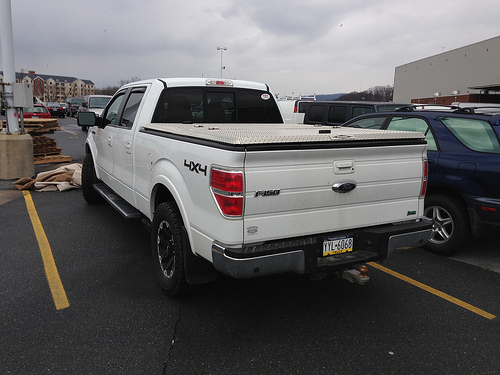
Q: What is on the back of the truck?
A: Silver cover.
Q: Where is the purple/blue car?
A: Right of the truck.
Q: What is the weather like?
A: Rainy.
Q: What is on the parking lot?
A: Cars.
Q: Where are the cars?
A: In the parking lot.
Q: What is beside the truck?
A: A car.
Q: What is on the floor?
A: A painted line.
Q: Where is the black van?
A: In the parking lot.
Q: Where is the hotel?
A: In the distance.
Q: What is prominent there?
A: Pickup truck.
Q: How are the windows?
A: Tinted.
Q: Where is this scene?
A: Parking lot.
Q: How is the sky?
A: Cloudy.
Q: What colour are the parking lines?
A: Yellow.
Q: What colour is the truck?
A: White.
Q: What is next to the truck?
A: Car.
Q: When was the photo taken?
A: Daytime.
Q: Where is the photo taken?
A: Parking lot.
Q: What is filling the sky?
A: Clouds.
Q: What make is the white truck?
A: Ford.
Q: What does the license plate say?
A: YYL 6068.